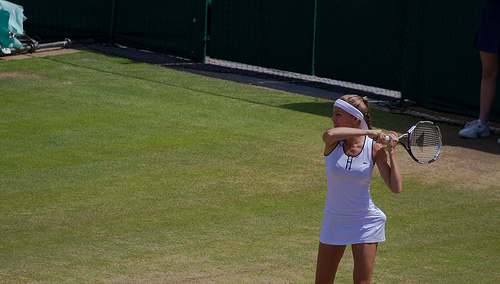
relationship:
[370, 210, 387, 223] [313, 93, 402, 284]
tennis ball inside girl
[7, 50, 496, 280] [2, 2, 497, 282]
grass on tennis court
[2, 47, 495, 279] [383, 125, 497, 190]
court has dirt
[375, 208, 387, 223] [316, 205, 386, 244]
tennis ball in shorts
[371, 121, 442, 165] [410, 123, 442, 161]
racket has wire frame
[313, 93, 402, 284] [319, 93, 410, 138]
girl wearing headband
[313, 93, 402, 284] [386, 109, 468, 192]
girl swinging racket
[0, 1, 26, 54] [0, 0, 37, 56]
tarp in corner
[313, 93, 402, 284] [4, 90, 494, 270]
girl in foreground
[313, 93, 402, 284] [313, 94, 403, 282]
girl wearing dress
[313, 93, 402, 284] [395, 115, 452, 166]
girl holding racquet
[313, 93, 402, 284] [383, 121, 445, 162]
girl swinging racket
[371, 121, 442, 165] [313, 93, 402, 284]
racket held by girl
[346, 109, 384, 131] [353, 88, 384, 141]
hair in pony tail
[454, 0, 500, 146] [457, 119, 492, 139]
person wearing shoe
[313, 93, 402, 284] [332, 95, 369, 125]
girl wearing sweatband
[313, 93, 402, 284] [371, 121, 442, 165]
girl wearing racket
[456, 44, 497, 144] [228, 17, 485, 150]
leg against wall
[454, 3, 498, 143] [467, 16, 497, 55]
person wearing shorts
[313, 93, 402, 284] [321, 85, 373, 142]
girl has head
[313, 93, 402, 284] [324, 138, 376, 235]
girl wearing dress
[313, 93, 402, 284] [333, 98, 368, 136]
girl wearing headband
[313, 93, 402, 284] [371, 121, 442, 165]
girl holding racket